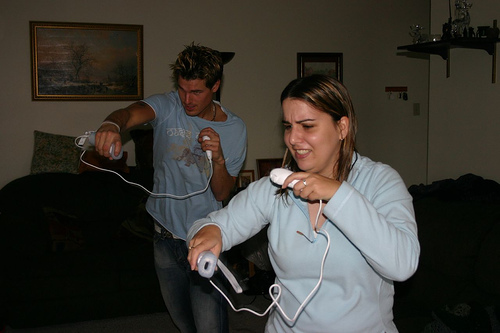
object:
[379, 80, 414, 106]
key holder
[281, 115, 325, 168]
woman's grimace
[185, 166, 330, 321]
wii mote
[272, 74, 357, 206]
girl/brown hair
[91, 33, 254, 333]
man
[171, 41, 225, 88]
hair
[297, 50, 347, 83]
picture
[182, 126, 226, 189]
remotes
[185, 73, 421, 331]
woman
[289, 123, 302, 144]
nose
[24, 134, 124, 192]
pillow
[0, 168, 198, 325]
couch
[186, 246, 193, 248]
ring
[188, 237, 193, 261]
finger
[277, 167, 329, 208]
hand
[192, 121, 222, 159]
hand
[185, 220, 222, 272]
hand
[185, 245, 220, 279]
remote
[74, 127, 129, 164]
remote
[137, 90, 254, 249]
tee shirt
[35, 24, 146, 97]
picture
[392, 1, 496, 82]
shelf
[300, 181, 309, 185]
ring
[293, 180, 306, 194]
finger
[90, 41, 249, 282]
controller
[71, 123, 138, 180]
wii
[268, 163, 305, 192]
remotes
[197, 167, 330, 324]
game controller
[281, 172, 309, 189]
finger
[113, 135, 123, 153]
finger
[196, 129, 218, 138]
finger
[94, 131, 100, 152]
finger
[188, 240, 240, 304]
wii remote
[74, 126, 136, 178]
wii remote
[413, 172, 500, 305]
couch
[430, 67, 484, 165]
wall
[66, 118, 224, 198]
game controller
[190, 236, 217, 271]
finger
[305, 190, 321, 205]
finger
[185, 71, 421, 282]
controller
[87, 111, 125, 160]
hand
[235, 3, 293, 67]
wall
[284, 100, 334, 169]
facial expression